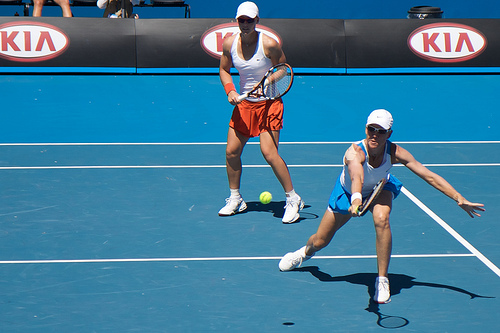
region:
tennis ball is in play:
[258, 189, 272, 207]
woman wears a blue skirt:
[328, 180, 402, 212]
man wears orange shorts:
[232, 101, 285, 133]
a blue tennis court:
[0, 139, 499, 331]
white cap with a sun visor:
[237, 2, 257, 24]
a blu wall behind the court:
[3, 62, 495, 139]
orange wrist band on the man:
[223, 81, 233, 93]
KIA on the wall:
[0, 20, 70, 62]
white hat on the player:
[365, 108, 393, 130]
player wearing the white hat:
[278, 107, 485, 302]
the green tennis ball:
[258, 191, 272, 204]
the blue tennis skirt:
[328, 175, 402, 214]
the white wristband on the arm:
[349, 190, 363, 201]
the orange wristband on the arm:
[223, 80, 235, 94]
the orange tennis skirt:
[228, 95, 284, 137]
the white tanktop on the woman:
[230, 30, 280, 100]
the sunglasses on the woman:
[236, 15, 256, 25]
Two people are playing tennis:
[215, 2, 484, 309]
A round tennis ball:
[254, 187, 274, 207]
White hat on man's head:
[232, 0, 263, 40]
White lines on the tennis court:
[2, 136, 498, 280]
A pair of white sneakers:
[277, 243, 394, 306]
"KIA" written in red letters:
[420, 25, 476, 57]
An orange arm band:
[222, 78, 236, 98]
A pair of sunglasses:
[363, 122, 392, 138]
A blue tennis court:
[2, 65, 499, 329]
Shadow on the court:
[281, 259, 497, 331]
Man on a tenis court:
[213, 3, 293, 233]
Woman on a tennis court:
[308, 99, 443, 309]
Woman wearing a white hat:
[360, 103, 405, 150]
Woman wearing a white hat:
[225, 3, 271, 34]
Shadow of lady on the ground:
[272, 230, 497, 321]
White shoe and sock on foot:
[203, 179, 248, 230]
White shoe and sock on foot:
[267, 188, 307, 228]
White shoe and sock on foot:
[275, 241, 320, 291]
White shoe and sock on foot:
[342, 267, 397, 317]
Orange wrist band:
[214, 74, 249, 102]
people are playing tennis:
[219, 3, 484, 304]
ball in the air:
[260, 190, 272, 201]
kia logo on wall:
[2, 20, 67, 60]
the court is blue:
[2, 69, 499, 329]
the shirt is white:
[232, 33, 277, 98]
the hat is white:
[366, 109, 391, 129]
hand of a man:
[455, 198, 485, 218]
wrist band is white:
[352, 190, 360, 201]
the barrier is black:
[0, 15, 498, 65]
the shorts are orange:
[229, 97, 284, 135]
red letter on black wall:
[0, 22, 23, 62]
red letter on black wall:
[18, 24, 37, 50]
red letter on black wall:
[36, 29, 61, 61]